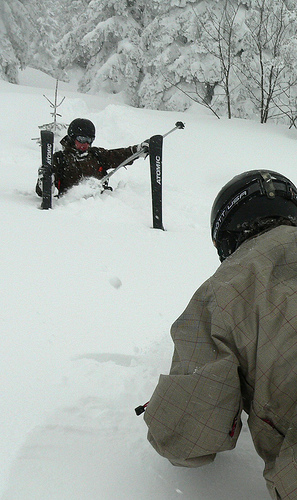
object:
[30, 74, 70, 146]
pinetree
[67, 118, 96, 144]
helmet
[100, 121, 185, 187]
pole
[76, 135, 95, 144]
snow goggles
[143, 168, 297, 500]
person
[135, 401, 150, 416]
tag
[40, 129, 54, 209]
ski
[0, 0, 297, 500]
snow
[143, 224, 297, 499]
coat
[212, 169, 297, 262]
head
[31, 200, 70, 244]
cnow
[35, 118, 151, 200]
man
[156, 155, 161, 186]
logo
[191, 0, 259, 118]
trees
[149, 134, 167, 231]
black skis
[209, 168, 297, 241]
helmet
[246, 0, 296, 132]
tree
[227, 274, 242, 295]
line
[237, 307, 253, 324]
line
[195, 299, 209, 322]
line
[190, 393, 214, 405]
line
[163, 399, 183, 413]
line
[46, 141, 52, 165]
writing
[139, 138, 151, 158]
hand